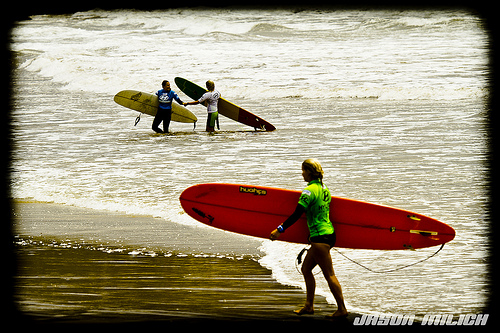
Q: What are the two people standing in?
A: Water.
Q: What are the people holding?
A: Surfboards.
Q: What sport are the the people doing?
A: Surfing.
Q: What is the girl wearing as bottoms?
A: Swimming suit.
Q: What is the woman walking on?
A: Sand.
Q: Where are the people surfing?
A: The beach.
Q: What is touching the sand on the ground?
A: The water.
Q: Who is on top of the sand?
A: The woman.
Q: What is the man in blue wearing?
A: A wetsuit.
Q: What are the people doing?
A: Surfing.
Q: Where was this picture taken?
A: At the ocean.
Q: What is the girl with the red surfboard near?
A: The shoreline of the ocean.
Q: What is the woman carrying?
A: A surfboard.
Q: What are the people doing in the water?
A: Shaking hands.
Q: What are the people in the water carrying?
A: Surfboards.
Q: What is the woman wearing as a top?
A: A rashboard.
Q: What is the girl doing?
A: Walking.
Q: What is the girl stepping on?
A: Sand.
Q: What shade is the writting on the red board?
A: Yellow.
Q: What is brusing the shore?
A: Water.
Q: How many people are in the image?
A: 3.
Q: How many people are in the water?
A: 2.